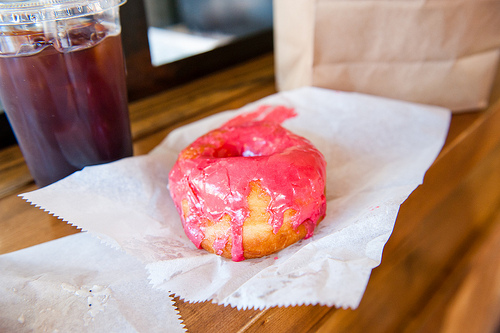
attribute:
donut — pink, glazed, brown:
[162, 122, 327, 264]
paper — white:
[18, 87, 455, 316]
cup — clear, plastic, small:
[2, 2, 137, 187]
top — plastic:
[2, 2, 129, 27]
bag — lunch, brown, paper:
[270, 2, 499, 113]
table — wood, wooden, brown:
[0, 50, 499, 332]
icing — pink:
[172, 119, 327, 258]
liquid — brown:
[2, 32, 134, 185]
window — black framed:
[0, 0, 274, 150]